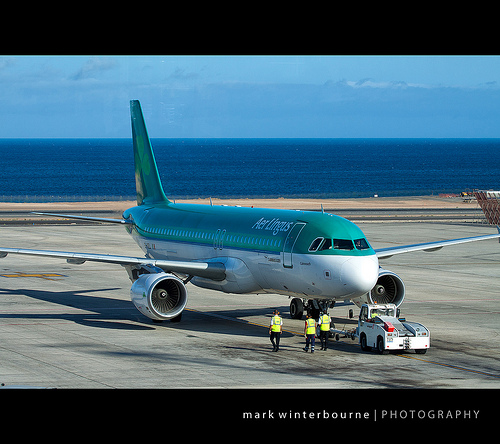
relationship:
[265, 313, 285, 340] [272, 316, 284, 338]
man in yellow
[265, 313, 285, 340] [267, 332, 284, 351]
man in jeans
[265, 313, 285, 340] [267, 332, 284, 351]
man in black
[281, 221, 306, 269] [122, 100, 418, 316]
door on plane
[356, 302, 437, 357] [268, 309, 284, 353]
carrier near man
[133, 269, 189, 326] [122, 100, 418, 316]
fan on plane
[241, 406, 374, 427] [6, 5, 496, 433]
person taking picture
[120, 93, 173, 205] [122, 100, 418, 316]
tail of plane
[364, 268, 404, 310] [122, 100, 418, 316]
left engine plane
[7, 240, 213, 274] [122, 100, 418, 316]
wing on plane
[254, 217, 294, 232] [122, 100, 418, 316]
white on plane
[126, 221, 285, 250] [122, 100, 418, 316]
windows on plane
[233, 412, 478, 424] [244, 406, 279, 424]
picture by mark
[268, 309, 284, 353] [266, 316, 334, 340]
man men controlling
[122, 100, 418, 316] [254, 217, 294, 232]
plane by aer lingus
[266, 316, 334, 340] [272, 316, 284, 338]
men in yellow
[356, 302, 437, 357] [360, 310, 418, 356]
cart of luggage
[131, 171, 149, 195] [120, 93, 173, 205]
clover on tail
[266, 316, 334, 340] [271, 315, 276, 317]
men in orange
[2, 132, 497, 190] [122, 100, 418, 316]
water behind plane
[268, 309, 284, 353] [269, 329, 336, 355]
man men walking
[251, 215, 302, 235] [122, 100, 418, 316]
name on plane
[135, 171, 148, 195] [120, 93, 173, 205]
clover on tail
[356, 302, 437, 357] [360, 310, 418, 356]
white vehicle parked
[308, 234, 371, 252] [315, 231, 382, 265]
windows in cockpit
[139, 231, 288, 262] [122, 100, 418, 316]
stripe on plane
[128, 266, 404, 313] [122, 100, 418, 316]
engines on plane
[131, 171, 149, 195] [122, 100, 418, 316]
clover on plane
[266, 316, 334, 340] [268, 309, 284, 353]
three working man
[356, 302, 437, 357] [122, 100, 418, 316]
vehicle for airport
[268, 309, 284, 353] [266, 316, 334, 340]
man wearing vests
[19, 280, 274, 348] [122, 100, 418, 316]
shadow behind plane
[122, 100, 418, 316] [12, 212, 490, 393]
plane on runway